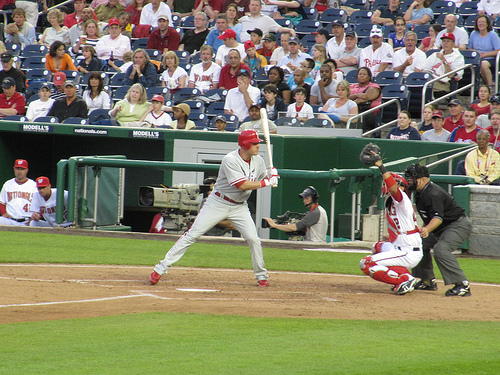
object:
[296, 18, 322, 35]
seats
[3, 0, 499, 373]
stadium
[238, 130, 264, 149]
helmet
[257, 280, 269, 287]
shoe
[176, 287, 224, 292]
plate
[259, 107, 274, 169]
bat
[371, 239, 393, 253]
shields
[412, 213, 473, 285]
pants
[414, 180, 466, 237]
shirt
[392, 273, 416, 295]
sneakers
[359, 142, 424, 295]
catcher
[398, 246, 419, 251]
belt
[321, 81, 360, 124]
fans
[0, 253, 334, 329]
baseball field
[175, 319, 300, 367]
grass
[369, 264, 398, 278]
pads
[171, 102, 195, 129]
woman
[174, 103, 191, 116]
hat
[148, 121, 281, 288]
baseball player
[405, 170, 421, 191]
mask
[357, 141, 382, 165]
baseball glove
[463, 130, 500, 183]
man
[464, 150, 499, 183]
shirt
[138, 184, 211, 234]
camera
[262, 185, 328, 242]
crew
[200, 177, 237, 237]
dug out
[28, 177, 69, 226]
player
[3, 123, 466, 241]
dugout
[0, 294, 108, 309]
baseline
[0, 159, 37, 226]
man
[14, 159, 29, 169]
cap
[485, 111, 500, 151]
woman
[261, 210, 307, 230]
camera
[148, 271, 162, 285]
shoes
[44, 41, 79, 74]
woman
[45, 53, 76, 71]
shirt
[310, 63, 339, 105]
face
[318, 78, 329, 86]
hand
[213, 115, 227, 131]
boy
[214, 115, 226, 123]
cap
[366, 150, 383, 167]
hand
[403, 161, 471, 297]
umpire